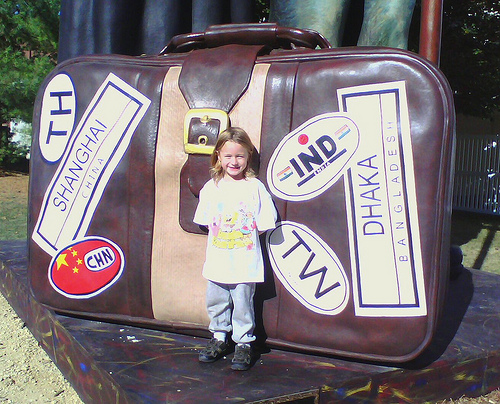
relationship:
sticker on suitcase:
[276, 118, 342, 180] [60, 46, 413, 81]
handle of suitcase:
[113, 8, 276, 43] [60, 46, 413, 81]